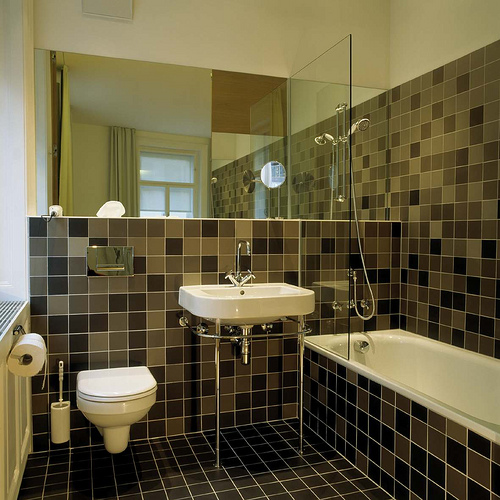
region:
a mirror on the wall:
[88, 70, 280, 212]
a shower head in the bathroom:
[355, 120, 368, 130]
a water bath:
[383, 346, 490, 396]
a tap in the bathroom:
[245, 246, 253, 260]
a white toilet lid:
[82, 371, 149, 390]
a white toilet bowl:
[81, 404, 155, 445]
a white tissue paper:
[18, 340, 39, 374]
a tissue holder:
[14, 328, 27, 336]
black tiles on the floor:
[241, 453, 291, 499]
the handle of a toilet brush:
[56, 362, 66, 399]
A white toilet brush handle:
[55, 360, 67, 407]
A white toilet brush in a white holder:
[49, 358, 73, 448]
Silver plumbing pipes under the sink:
[221, 323, 263, 370]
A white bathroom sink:
[181, 241, 318, 323]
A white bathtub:
[312, 316, 496, 470]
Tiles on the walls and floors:
[50, 48, 469, 496]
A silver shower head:
[342, 110, 369, 160]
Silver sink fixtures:
[222, 225, 265, 295]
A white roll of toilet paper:
[7, 320, 54, 377]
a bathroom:
[7, 5, 498, 477]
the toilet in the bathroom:
[76, 357, 153, 440]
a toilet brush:
[47, 360, 72, 433]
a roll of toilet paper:
[9, 337, 49, 376]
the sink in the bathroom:
[170, 268, 345, 331]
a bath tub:
[325, 289, 496, 448]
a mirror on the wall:
[43, 48, 357, 230]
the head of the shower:
[344, 113, 371, 140]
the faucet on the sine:
[227, 238, 267, 284]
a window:
[139, 125, 214, 215]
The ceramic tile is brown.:
[162, 235, 185, 258]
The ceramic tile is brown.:
[198, 218, 219, 238]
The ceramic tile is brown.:
[66, 214, 91, 239]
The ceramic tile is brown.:
[46, 253, 69, 278]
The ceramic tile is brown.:
[46, 273, 69, 297]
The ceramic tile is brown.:
[46, 311, 69, 337]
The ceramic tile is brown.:
[66, 311, 89, 333]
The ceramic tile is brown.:
[86, 309, 108, 337]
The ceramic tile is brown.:
[105, 291, 130, 313]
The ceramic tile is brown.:
[126, 290, 148, 314]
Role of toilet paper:
[5, 330, 50, 387]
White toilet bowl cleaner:
[47, 356, 74, 450]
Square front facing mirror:
[23, 42, 288, 218]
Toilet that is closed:
[69, 359, 165, 456]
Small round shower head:
[343, 111, 373, 138]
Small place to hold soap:
[82, 241, 138, 278]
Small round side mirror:
[241, 157, 293, 194]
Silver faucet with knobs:
[225, 238, 255, 287]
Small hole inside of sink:
[234, 286, 250, 299]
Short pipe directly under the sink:
[233, 323, 253, 365]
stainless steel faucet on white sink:
[179, 235, 317, 325]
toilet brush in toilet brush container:
[51, 359, 71, 443]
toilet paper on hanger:
[5, 325, 47, 391]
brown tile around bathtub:
[302, 325, 498, 498]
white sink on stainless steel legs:
[176, 281, 317, 468]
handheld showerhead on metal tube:
[335, 117, 376, 322]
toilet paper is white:
[5, 333, 47, 390]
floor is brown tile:
[17, 418, 397, 498]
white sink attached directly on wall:
[180, 267, 310, 361]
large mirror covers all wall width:
[23, 40, 390, 234]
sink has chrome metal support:
[183, 316, 314, 474]